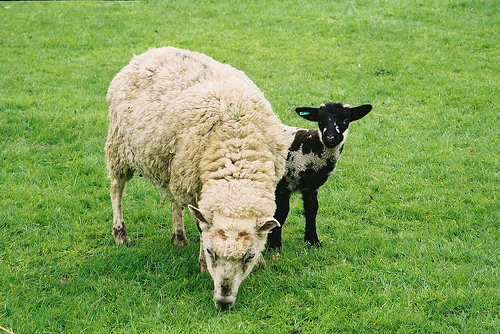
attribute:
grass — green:
[395, 22, 483, 101]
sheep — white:
[97, 42, 289, 316]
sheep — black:
[275, 99, 375, 250]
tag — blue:
[297, 108, 314, 118]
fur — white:
[199, 105, 270, 172]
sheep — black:
[263, 98, 373, 253]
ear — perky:
[183, 201, 215, 227]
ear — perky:
[255, 213, 281, 235]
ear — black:
[294, 102, 323, 124]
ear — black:
[346, 103, 373, 120]